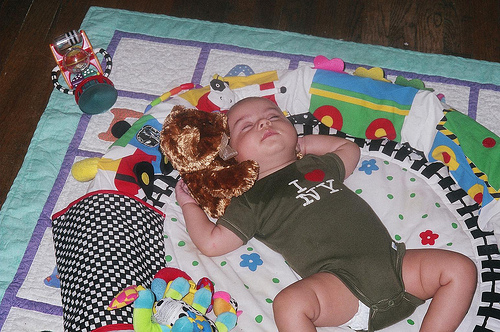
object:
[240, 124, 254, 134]
eye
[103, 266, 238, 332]
toy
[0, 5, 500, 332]
blanket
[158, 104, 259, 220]
bear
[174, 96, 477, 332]
baby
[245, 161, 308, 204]
spot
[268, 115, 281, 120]
eye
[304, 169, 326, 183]
heart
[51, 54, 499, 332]
bed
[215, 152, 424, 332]
onesie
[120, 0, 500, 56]
floor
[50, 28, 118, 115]
toy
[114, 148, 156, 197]
car/blanket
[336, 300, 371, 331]
diaper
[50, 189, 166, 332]
checkered blanket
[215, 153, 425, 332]
clothes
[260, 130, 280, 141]
mouth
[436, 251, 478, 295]
knee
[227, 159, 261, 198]
paw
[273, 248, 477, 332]
legs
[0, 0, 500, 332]
ground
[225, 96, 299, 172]
head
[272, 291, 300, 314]
knee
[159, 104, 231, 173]
head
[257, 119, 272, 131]
nose